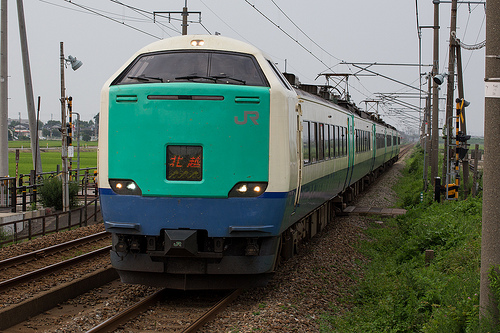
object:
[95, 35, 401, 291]
train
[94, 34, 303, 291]
front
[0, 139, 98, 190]
grass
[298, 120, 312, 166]
windows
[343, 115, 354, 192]
door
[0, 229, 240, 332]
track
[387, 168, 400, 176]
rocks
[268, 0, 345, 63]
lines